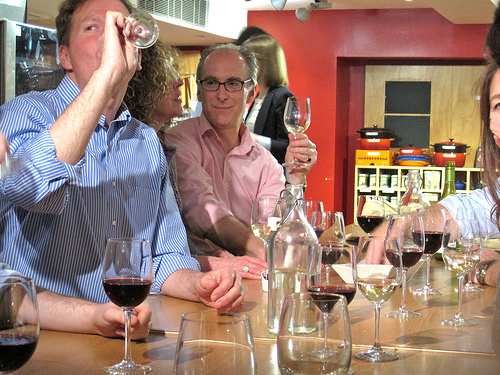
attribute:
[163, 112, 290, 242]
shirt — pink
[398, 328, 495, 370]
table — part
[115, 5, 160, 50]
glass — part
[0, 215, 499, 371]
table — part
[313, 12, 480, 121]
wall — part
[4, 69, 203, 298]
shirt — striped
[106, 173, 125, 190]
button — white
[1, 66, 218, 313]
shirt — blue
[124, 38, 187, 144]
hair — curly, short, blond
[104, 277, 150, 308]
wine — red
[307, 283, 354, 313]
wine — red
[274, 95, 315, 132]
wine glass — clear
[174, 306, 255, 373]
wine glass — clear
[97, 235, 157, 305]
wine glass — clear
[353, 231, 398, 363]
wine glass — clear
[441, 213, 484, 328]
wine glass — clear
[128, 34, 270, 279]
woman — blonde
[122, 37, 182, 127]
hair — curly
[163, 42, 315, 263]
man — bald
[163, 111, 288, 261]
shirt — pink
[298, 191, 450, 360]
wine glasses — half full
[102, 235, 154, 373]
wine glasses — half full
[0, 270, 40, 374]
wine glasses — half full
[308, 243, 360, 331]
glass — part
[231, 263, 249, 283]
ring — silver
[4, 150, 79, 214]
elbow — part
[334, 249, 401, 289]
dish — white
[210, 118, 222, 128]
chin — part